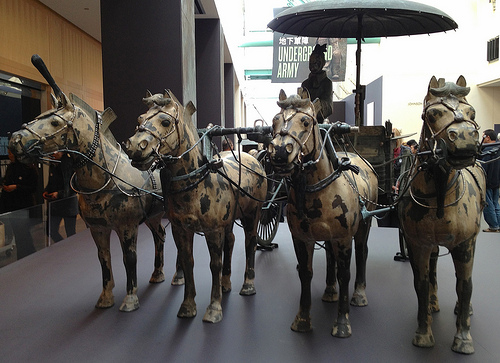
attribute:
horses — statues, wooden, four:
[44, 87, 499, 331]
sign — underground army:
[274, 25, 356, 80]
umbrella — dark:
[273, 8, 459, 36]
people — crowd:
[396, 130, 499, 201]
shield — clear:
[0, 197, 82, 242]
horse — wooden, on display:
[33, 111, 183, 277]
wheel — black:
[236, 185, 293, 253]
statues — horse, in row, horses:
[28, 85, 498, 340]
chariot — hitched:
[259, 119, 379, 201]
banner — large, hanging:
[269, 5, 353, 83]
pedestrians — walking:
[0, 150, 80, 233]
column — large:
[104, 2, 200, 171]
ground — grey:
[37, 224, 461, 362]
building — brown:
[8, 7, 498, 199]